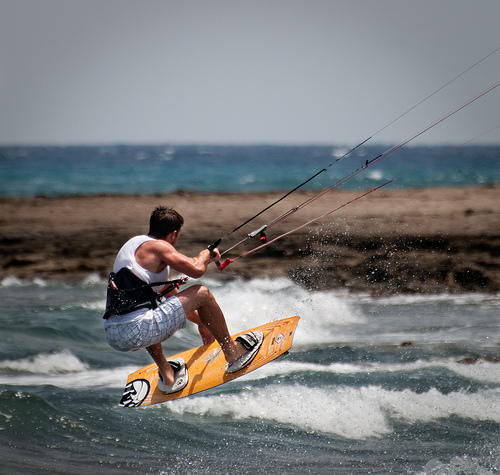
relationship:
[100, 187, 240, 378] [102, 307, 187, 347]
man wears shorts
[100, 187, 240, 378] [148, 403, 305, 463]
man catches air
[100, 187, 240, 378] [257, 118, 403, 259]
man holds lines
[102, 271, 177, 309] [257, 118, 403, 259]
harness for lines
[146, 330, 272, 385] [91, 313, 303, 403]
foot straps for board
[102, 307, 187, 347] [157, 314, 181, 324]
trunks have stripes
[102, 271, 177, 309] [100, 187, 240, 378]
harness for man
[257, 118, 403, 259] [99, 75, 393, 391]
lines for parasailing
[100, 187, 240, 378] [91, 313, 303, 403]
man on board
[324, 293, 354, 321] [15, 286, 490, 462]
foam in ocean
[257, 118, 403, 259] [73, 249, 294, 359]
lines for skiing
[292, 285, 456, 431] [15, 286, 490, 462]
waves in ocean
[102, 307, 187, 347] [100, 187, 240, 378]
shorts on man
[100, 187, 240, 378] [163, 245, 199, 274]
man has muscles